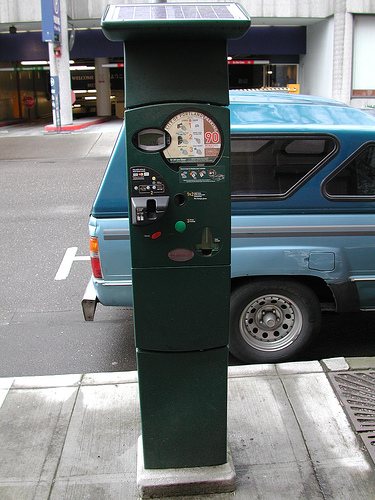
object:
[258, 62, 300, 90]
window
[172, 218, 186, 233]
button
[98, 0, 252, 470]
parking meter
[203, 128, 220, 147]
number 90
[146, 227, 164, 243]
button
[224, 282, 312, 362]
tire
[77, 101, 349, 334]
van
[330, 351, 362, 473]
plate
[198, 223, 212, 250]
slot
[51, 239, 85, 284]
line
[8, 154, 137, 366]
road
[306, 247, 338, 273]
cover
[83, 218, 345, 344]
truck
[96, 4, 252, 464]
post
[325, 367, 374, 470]
grate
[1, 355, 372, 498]
sidewalk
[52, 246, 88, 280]
lines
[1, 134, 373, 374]
street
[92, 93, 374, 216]
camper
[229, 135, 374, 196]
windows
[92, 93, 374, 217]
camper shell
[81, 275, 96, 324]
bumper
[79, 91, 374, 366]
truck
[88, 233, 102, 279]
brake light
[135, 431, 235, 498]
base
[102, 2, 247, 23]
solar panel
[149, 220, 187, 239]
buttons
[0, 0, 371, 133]
parking garage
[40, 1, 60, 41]
sign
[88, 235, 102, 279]
lights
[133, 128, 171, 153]
display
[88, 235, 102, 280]
tail light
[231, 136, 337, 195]
window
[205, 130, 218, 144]
90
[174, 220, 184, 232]
button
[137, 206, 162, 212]
slot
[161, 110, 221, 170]
instructions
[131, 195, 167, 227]
credit card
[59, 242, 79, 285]
line painted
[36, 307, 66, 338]
pavement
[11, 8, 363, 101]
buildiing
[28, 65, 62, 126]
window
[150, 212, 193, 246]
button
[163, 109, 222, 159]
sticker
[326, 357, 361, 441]
drain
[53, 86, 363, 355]
car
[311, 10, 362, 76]
building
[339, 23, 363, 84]
window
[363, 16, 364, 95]
window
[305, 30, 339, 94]
wall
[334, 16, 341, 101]
wall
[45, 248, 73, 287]
spot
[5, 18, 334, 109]
garage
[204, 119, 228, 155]
number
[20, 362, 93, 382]
curb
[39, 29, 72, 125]
pole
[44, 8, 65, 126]
center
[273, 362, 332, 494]
crack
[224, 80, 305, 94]
barrier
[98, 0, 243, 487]
meter